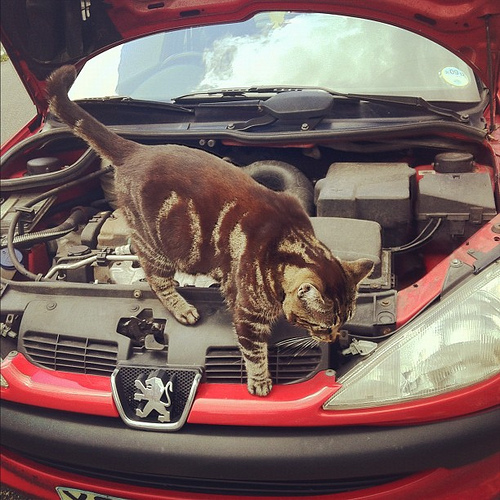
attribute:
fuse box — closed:
[414, 171, 498, 254]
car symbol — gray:
[121, 370, 177, 423]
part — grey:
[305, 215, 383, 277]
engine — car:
[2, 133, 496, 299]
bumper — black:
[2, 399, 499, 484]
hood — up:
[0, 0, 499, 100]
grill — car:
[20, 306, 330, 396]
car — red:
[3, 1, 496, 498]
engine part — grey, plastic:
[241, 157, 316, 212]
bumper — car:
[7, 400, 473, 480]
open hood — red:
[0, 2, 499, 349]